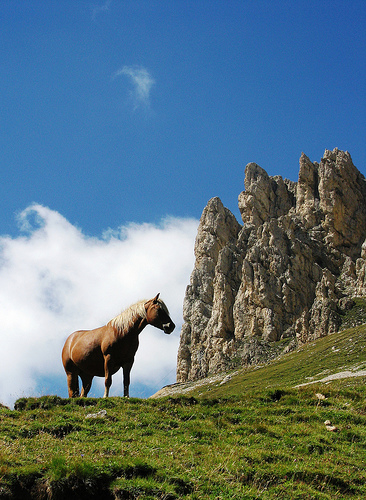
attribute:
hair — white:
[104, 292, 147, 330]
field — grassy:
[1, 389, 364, 462]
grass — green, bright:
[142, 396, 301, 482]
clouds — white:
[4, 198, 191, 391]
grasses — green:
[192, 375, 260, 431]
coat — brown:
[76, 337, 97, 349]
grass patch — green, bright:
[1, 324, 364, 499]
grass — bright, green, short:
[0, 321, 365, 498]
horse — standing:
[94, 290, 184, 360]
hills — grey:
[237, 199, 305, 294]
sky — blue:
[3, 2, 361, 230]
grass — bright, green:
[11, 377, 356, 498]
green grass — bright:
[227, 351, 350, 401]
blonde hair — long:
[101, 295, 187, 342]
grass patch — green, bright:
[241, 407, 349, 493]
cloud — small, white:
[103, 55, 168, 130]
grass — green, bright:
[225, 389, 292, 426]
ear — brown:
[143, 282, 177, 306]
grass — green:
[131, 413, 276, 498]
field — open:
[12, 357, 364, 498]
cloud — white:
[7, 214, 177, 306]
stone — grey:
[177, 139, 364, 389]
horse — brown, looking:
[55, 288, 176, 398]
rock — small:
[319, 412, 342, 435]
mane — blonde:
[108, 294, 153, 331]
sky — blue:
[2, 0, 362, 390]